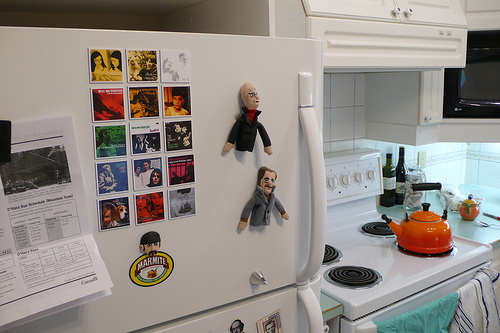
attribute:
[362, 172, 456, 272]
teakettle — orange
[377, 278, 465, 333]
towels — green, striped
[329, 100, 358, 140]
tile — white, square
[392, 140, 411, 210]
bottle — black, wine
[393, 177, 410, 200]
label — white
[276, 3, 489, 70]
cabinet — kitchen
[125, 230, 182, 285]
magnet — refrigerator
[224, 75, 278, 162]
magnet — frig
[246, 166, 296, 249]
magnet — frig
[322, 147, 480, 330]
stove — white, electric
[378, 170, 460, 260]
kettle — tea, orange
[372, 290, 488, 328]
towel — part of, blue, tea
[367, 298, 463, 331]
towel — tea, part of, striped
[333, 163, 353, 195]
knob — control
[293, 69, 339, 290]
handle — freezer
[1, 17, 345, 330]
frig — white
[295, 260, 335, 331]
handle — part of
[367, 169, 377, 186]
knob — control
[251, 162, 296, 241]
magnet — refrigerator, person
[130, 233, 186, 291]
magnet — cartoon, refridgerator, member of beatles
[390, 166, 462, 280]
teapot — orange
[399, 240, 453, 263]
burner — stove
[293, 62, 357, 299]
handle — white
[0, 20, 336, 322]
door — freezer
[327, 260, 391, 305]
burner — black, metal, stovetop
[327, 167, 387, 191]
nobs — white, stove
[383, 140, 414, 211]
bottles — oil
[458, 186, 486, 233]
bowl — small, orange, ceramic, sugar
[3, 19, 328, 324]
refrigerator — white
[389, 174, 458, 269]
kettle — orange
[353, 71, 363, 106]
tile — white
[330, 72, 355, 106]
tile — white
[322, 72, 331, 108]
tile — white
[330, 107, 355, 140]
tile — white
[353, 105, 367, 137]
tile — white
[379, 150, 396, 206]
bottle — green, glass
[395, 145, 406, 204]
bottle — green, glass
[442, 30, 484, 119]
microwave oven — black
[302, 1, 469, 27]
kitchen cabinet — white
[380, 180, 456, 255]
tea kettle — orange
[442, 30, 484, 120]
microwave — black